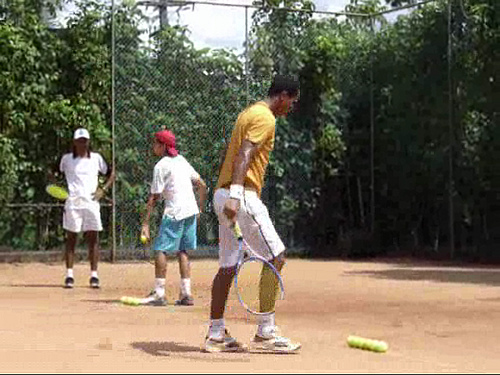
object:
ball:
[373, 340, 389, 354]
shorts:
[62, 207, 104, 234]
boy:
[137, 130, 207, 306]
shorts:
[152, 214, 198, 253]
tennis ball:
[119, 295, 134, 306]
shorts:
[211, 186, 288, 270]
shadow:
[341, 267, 498, 288]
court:
[1, 256, 498, 373]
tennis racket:
[42, 183, 70, 202]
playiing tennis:
[197, 113, 302, 355]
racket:
[225, 211, 286, 317]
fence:
[109, 0, 497, 256]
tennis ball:
[139, 233, 169, 253]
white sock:
[208, 317, 225, 337]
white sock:
[177, 278, 192, 297]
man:
[199, 78, 302, 357]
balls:
[367, 340, 380, 351]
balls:
[360, 340, 373, 351]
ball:
[345, 335, 356, 347]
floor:
[140, 352, 309, 374]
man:
[58, 125, 116, 288]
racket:
[45, 177, 70, 201]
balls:
[353, 337, 365, 348]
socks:
[257, 312, 276, 339]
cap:
[153, 129, 178, 157]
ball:
[138, 234, 148, 244]